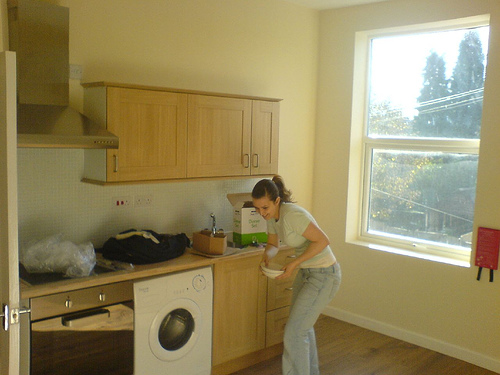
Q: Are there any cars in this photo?
A: No, there are no cars.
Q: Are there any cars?
A: No, there are no cars.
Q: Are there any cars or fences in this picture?
A: No, there are no cars or fences.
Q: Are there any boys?
A: No, there are no boys.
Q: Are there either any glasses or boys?
A: No, there are no boys or glasses.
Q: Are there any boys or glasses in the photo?
A: No, there are no boys or glasses.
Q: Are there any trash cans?
A: No, there are no trash cans.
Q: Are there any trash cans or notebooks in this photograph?
A: No, there are no trash cans or notebooks.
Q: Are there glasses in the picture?
A: No, there are no glasses.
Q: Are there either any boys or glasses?
A: No, there are no glasses or boys.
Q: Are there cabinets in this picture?
A: Yes, there is a cabinet.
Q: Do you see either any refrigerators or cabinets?
A: Yes, there is a cabinet.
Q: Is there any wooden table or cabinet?
A: Yes, there is a wood cabinet.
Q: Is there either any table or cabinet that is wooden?
A: Yes, the cabinet is wooden.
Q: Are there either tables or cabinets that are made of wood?
A: Yes, the cabinet is made of wood.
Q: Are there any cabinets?
A: Yes, there is a cabinet.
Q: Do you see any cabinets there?
A: Yes, there is a cabinet.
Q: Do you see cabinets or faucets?
A: Yes, there is a cabinet.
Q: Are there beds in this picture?
A: No, there are no beds.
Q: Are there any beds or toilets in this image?
A: No, there are no beds or toilets.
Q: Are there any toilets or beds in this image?
A: No, there are no beds or toilets.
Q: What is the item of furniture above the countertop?
A: The piece of furniture is a cabinet.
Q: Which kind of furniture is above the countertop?
A: The piece of furniture is a cabinet.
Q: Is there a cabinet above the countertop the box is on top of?
A: Yes, there is a cabinet above the countertop.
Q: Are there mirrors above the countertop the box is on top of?
A: No, there is a cabinet above the countertop.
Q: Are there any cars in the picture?
A: No, there are no cars.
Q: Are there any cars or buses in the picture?
A: No, there are no cars or buses.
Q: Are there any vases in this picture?
A: No, there are no vases.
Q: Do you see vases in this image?
A: No, there are no vases.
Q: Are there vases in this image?
A: No, there are no vases.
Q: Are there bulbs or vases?
A: No, there are no vases or bulbs.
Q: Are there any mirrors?
A: No, there are no mirrors.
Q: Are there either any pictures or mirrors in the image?
A: No, there are no mirrors or pictures.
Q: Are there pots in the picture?
A: No, there are no pots.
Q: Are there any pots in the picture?
A: No, there are no pots.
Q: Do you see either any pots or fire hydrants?
A: No, there are no pots or fire hydrants.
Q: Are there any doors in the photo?
A: Yes, there is a door.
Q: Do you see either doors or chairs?
A: Yes, there is a door.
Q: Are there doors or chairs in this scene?
A: Yes, there is a door.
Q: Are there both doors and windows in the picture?
A: Yes, there are both a door and a window.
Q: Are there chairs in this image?
A: No, there are no chairs.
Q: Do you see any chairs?
A: No, there are no chairs.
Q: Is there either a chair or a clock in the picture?
A: No, there are no chairs or clocks.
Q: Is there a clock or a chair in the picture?
A: No, there are no chairs or clocks.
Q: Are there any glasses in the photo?
A: No, there are no glasses.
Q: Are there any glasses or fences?
A: No, there are no glasses or fences.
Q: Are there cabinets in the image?
A: Yes, there is a cabinet.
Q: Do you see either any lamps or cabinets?
A: Yes, there is a cabinet.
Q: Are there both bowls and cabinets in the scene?
A: Yes, there are both a cabinet and a bowl.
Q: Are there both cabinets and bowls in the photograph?
A: Yes, there are both a cabinet and a bowl.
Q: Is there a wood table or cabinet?
A: Yes, there is a wood cabinet.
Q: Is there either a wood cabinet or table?
A: Yes, there is a wood cabinet.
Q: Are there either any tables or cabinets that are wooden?
A: Yes, the cabinet is wooden.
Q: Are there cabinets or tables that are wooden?
A: Yes, the cabinet is wooden.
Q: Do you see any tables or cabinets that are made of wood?
A: Yes, the cabinet is made of wood.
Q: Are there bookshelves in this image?
A: No, there are no bookshelves.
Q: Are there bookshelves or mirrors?
A: No, there are no bookshelves or mirrors.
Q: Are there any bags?
A: Yes, there is a bag.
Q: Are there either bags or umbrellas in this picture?
A: Yes, there is a bag.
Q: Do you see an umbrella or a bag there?
A: Yes, there is a bag.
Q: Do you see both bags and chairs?
A: No, there is a bag but no chairs.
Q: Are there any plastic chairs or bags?
A: Yes, there is a plastic bag.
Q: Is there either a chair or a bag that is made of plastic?
A: Yes, the bag is made of plastic.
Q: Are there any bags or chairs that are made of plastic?
A: Yes, the bag is made of plastic.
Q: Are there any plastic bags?
A: Yes, there is a bag that is made of plastic.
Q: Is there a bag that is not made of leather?
A: Yes, there is a bag that is made of plastic.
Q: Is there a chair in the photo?
A: No, there are no chairs.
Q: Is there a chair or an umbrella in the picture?
A: No, there are no chairs or umbrellas.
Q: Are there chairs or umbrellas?
A: No, there are no chairs or umbrellas.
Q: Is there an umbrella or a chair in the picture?
A: No, there are no chairs or umbrellas.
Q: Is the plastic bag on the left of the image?
A: Yes, the bag is on the left of the image.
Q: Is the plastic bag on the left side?
A: Yes, the bag is on the left of the image.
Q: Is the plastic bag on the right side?
A: No, the bag is on the left of the image.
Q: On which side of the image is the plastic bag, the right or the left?
A: The bag is on the left of the image.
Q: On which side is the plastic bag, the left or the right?
A: The bag is on the left of the image.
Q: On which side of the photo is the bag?
A: The bag is on the left of the image.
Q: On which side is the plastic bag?
A: The bag is on the left of the image.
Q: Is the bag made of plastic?
A: Yes, the bag is made of plastic.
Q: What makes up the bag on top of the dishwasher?
A: The bag is made of plastic.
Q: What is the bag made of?
A: The bag is made of plastic.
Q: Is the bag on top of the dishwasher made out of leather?
A: No, the bag is made of plastic.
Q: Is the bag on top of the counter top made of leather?
A: No, the bag is made of plastic.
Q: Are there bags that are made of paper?
A: No, there is a bag but it is made of plastic.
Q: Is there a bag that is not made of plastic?
A: No, there is a bag but it is made of plastic.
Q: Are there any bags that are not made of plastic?
A: No, there is a bag but it is made of plastic.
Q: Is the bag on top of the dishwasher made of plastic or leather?
A: The bag is made of plastic.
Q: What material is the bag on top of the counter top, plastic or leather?
A: The bag is made of plastic.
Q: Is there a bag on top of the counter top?
A: Yes, there is a bag on top of the counter top.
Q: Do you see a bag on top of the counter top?
A: Yes, there is a bag on top of the counter top.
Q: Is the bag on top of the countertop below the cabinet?
A: Yes, the bag is on top of the countertop.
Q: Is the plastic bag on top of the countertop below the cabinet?
A: Yes, the bag is on top of the countertop.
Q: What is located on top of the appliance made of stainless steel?
A: The bag is on top of the dishwasher.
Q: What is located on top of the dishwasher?
A: The bag is on top of the dishwasher.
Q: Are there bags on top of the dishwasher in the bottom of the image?
A: Yes, there is a bag on top of the dishwasher.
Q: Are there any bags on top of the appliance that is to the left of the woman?
A: Yes, there is a bag on top of the dishwasher.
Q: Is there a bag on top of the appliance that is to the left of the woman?
A: Yes, there is a bag on top of the dishwasher.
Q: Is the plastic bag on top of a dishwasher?
A: Yes, the bag is on top of a dishwasher.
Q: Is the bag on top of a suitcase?
A: No, the bag is on top of a dishwasher.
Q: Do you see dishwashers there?
A: Yes, there is a dishwasher.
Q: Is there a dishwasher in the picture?
A: Yes, there is a dishwasher.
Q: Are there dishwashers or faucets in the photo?
A: Yes, there is a dishwasher.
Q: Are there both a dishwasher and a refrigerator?
A: No, there is a dishwasher but no refrigerators.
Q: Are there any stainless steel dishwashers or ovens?
A: Yes, there is a stainless steel dishwasher.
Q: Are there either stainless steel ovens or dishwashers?
A: Yes, there is a stainless steel dishwasher.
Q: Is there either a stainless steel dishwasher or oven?
A: Yes, there is a stainless steel dishwasher.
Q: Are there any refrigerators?
A: No, there are no refrigerators.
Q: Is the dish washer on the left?
A: Yes, the dish washer is on the left of the image.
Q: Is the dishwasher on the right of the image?
A: No, the dishwasher is on the left of the image.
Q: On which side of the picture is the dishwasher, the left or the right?
A: The dishwasher is on the left of the image.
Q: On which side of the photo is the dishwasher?
A: The dishwasher is on the left of the image.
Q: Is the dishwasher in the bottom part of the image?
A: Yes, the dishwasher is in the bottom of the image.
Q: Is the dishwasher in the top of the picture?
A: No, the dishwasher is in the bottom of the image.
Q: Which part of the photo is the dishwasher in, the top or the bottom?
A: The dishwasher is in the bottom of the image.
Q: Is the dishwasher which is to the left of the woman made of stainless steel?
A: Yes, the dish washer is made of stainless steel.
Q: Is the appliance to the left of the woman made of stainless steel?
A: Yes, the dish washer is made of stainless steel.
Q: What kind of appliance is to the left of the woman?
A: The appliance is a dishwasher.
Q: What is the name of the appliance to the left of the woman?
A: The appliance is a dishwasher.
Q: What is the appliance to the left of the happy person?
A: The appliance is a dishwasher.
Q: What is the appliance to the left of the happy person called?
A: The appliance is a dishwasher.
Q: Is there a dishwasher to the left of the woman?
A: Yes, there is a dishwasher to the left of the woman.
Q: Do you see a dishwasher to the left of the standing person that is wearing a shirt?
A: Yes, there is a dishwasher to the left of the woman.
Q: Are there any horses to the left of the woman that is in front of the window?
A: No, there is a dishwasher to the left of the woman.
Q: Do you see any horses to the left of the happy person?
A: No, there is a dishwasher to the left of the woman.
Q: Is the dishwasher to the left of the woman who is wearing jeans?
A: Yes, the dishwasher is to the left of the woman.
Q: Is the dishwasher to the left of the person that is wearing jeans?
A: Yes, the dishwasher is to the left of the woman.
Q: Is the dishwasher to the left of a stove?
A: No, the dishwasher is to the left of the woman.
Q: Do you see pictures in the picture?
A: No, there are no pictures.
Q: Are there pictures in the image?
A: No, there are no pictures.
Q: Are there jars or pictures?
A: No, there are no pictures or jars.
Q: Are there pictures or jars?
A: No, there are no pictures or jars.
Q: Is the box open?
A: Yes, the box is open.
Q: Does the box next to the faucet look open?
A: Yes, the box is open.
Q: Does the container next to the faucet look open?
A: Yes, the box is open.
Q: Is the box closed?
A: No, the box is open.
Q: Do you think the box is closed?
A: No, the box is open.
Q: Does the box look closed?
A: No, the box is open.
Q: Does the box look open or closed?
A: The box is open.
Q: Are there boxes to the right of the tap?
A: Yes, there is a box to the right of the tap.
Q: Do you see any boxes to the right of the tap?
A: Yes, there is a box to the right of the tap.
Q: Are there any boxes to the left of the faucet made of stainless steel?
A: No, the box is to the right of the tap.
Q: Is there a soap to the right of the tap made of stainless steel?
A: No, there is a box to the right of the faucet.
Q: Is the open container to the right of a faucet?
A: Yes, the box is to the right of a faucet.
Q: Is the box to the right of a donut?
A: No, the box is to the right of a faucet.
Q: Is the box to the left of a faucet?
A: No, the box is to the right of a faucet.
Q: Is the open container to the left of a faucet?
A: No, the box is to the right of a faucet.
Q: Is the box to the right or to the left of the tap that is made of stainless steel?
A: The box is to the right of the tap.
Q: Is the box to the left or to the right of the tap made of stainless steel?
A: The box is to the right of the tap.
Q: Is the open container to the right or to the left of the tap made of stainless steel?
A: The box is to the right of the tap.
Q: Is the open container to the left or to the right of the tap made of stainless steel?
A: The box is to the right of the tap.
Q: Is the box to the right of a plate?
A: Yes, the box is to the right of a plate.